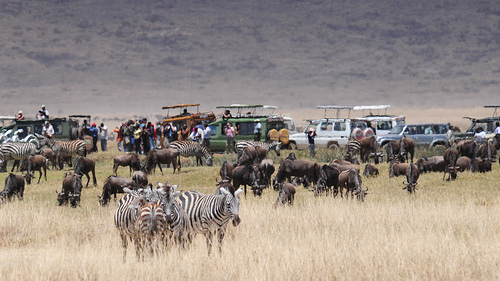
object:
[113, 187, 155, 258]
zebra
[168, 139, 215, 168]
zebra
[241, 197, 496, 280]
grass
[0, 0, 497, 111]
hillside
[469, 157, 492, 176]
animals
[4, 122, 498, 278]
ground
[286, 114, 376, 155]
vehicle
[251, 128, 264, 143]
people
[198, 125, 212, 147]
people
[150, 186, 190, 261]
animals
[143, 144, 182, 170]
animals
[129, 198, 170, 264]
zebra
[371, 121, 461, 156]
vehicle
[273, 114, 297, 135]
truck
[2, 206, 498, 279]
field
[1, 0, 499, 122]
plains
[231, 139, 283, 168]
zebra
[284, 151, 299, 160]
cattle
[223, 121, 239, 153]
person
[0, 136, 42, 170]
zebra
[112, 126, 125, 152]
people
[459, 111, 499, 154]
vehicles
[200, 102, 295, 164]
safari vehicle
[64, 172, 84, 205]
animal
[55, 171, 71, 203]
animal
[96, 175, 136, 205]
animal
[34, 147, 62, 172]
animal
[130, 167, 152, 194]
animal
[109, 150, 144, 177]
animal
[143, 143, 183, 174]
animal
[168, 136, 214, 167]
animal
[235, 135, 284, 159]
animal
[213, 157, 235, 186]
animal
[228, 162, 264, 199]
animal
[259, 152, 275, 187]
animal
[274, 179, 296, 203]
animal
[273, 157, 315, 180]
animal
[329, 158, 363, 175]
animal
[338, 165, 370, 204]
animal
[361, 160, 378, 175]
animal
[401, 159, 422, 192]
animal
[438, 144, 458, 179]
animal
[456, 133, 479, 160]
animal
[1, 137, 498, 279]
grass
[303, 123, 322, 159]
person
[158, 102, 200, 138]
car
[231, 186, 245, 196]
ears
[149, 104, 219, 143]
vehicle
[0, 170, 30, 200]
animal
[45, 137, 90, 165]
zebra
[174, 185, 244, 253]
zebra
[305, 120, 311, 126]
hat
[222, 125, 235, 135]
shirt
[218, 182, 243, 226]
head